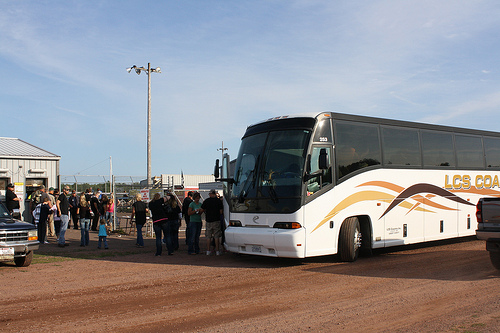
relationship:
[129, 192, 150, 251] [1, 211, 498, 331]
person on ground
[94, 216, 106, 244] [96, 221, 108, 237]
girl wearing a shirt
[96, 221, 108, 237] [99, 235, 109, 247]
shirt and jeans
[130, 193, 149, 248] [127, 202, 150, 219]
person in a shirt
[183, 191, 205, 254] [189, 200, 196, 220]
woman wearing shirt